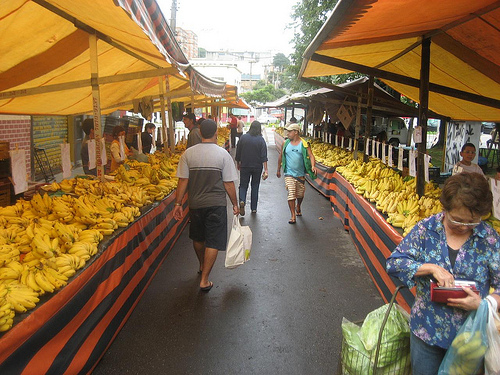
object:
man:
[171, 119, 243, 289]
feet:
[200, 280, 212, 288]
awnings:
[0, 0, 227, 104]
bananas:
[36, 250, 60, 258]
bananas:
[96, 224, 109, 233]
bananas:
[130, 175, 153, 189]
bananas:
[35, 189, 45, 211]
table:
[0, 184, 163, 371]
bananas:
[352, 154, 374, 168]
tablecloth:
[0, 244, 124, 370]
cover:
[344, 206, 387, 275]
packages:
[340, 284, 407, 375]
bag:
[438, 301, 487, 373]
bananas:
[455, 340, 488, 354]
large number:
[0, 134, 414, 332]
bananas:
[85, 186, 103, 198]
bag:
[224, 212, 252, 267]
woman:
[382, 170, 498, 373]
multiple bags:
[484, 296, 498, 374]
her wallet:
[431, 278, 480, 303]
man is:
[276, 123, 317, 224]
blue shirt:
[284, 139, 305, 176]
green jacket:
[282, 136, 317, 180]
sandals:
[200, 281, 215, 292]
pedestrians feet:
[288, 216, 297, 223]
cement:
[112, 147, 381, 369]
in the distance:
[158, 1, 337, 120]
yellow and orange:
[2, 2, 498, 121]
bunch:
[403, 212, 417, 228]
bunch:
[19, 263, 67, 295]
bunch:
[395, 199, 421, 214]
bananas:
[372, 176, 397, 196]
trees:
[300, 1, 363, 89]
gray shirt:
[174, 139, 239, 211]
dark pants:
[189, 206, 229, 252]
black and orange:
[317, 173, 405, 301]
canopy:
[1, 1, 153, 109]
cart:
[338, 283, 410, 374]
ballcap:
[285, 124, 301, 132]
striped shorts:
[284, 176, 307, 202]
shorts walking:
[286, 175, 309, 224]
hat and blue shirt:
[281, 123, 307, 178]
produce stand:
[0, 1, 500, 369]